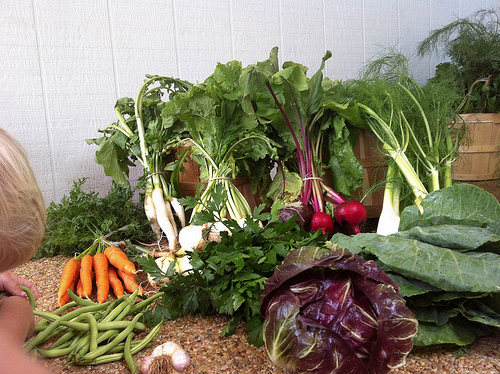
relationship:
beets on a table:
[237, 45, 369, 240] [20, 246, 392, 372]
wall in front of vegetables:
[0, 0, 497, 206] [20, 38, 499, 372]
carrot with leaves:
[57, 245, 145, 307] [26, 170, 153, 257]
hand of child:
[0, 267, 40, 298] [0, 122, 64, 372]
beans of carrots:
[14, 285, 166, 374] [52, 245, 154, 302]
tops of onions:
[174, 70, 266, 175] [164, 211, 231, 249]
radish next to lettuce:
[296, 192, 339, 242] [258, 224, 435, 371]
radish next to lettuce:
[327, 181, 371, 241] [258, 224, 435, 371]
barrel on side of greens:
[321, 108, 498, 220] [86, 43, 480, 256]